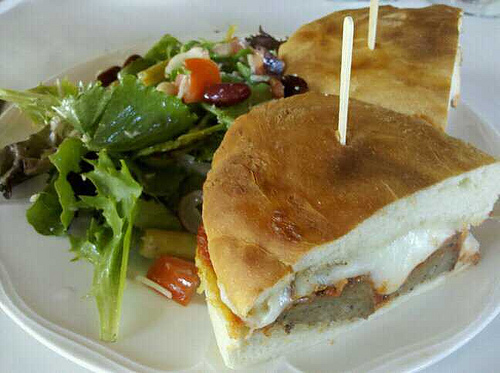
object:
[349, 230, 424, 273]
cheese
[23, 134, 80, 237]
leaf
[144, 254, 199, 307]
tomato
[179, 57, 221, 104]
pepper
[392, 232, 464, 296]
meat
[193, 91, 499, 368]
sandwich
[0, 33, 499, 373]
plate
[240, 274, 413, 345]
meatball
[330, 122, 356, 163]
pick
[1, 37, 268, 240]
salad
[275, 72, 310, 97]
olive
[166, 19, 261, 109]
crouton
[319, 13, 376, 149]
stick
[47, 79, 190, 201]
lettuce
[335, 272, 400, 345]
ketchup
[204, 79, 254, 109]
bean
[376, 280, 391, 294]
sauce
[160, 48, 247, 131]
pepperoni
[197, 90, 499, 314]
bread